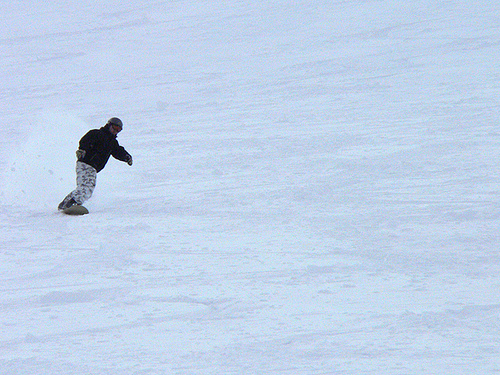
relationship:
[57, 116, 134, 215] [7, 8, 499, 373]
man coming down mountainside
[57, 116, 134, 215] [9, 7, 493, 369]
man on snow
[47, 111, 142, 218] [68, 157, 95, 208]
snowboarder wearing pants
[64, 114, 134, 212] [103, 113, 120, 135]
snowboarder wearing cap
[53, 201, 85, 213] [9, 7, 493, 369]
snowboard in snow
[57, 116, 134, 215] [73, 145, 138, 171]
man wearing gloves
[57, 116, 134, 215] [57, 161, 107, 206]
man has pants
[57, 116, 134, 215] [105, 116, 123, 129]
man wears cap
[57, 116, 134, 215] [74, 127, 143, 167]
man wearing a coat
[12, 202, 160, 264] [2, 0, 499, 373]
tracks in snowfall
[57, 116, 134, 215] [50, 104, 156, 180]
man wearing jacket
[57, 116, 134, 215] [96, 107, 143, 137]
man wearing mask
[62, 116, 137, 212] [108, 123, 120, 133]
man wearing goggles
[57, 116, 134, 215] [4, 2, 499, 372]
man snowboarding hill